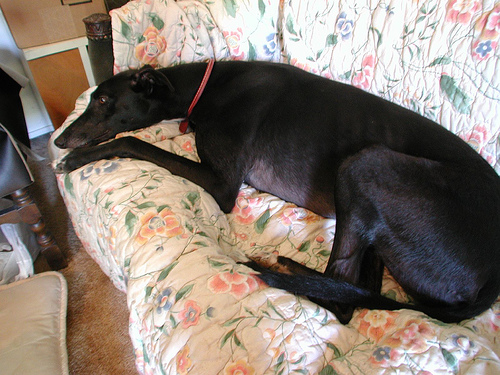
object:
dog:
[53, 59, 500, 325]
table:
[0, 68, 68, 271]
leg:
[12, 186, 68, 271]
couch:
[48, 1, 500, 374]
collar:
[177, 60, 215, 134]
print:
[439, 71, 471, 116]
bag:
[0, 223, 38, 280]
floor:
[0, 128, 140, 374]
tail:
[254, 274, 420, 310]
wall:
[1, 0, 106, 131]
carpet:
[0, 134, 129, 375]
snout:
[53, 136, 67, 149]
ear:
[131, 63, 175, 98]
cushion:
[0, 270, 70, 374]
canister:
[83, 12, 116, 87]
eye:
[100, 96, 107, 103]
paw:
[55, 151, 82, 173]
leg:
[236, 224, 369, 326]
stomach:
[242, 156, 336, 218]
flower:
[352, 56, 375, 92]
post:
[80, 13, 117, 87]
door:
[0, 7, 56, 142]